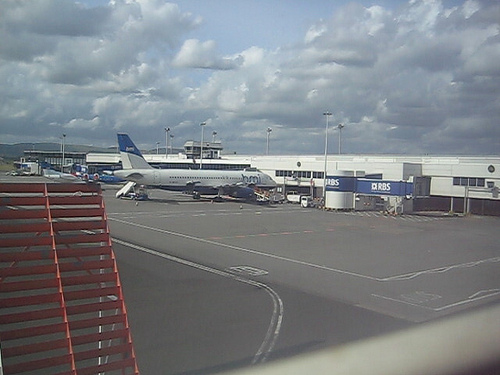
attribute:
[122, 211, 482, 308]
lines — white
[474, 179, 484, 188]
window — large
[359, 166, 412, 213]
sign — white, blue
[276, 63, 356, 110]
clouds — heavy, white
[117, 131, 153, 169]
tail — white, blue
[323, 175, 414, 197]
logo — blue, white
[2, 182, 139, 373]
red steel — tall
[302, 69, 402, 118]
gray — white, cloudy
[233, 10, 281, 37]
sky — grey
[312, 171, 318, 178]
window — white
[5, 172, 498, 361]
tarmac — dark grey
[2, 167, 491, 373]
walkway — blue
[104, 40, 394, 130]
clouds — dark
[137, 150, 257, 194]
windows — dark, plentiful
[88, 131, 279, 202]
airplane — white, large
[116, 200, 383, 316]
line — white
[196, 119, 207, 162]
lightposts — tall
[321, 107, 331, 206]
lightposts — tall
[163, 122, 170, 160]
lightposts — tall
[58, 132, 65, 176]
lightposts — tall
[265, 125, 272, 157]
lightposts — tall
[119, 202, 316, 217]
line — red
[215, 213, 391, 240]
line — red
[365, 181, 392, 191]
painted logo — white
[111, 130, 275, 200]
airplane — large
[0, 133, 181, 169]
mountains — large, distant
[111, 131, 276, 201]
plane — blue, white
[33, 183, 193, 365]
tail — white, blue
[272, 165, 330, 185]
windows — black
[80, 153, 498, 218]
building — white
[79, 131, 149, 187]
tail — blue, white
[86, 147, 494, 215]
building — large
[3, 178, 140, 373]
structure — red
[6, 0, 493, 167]
sky — white, blue